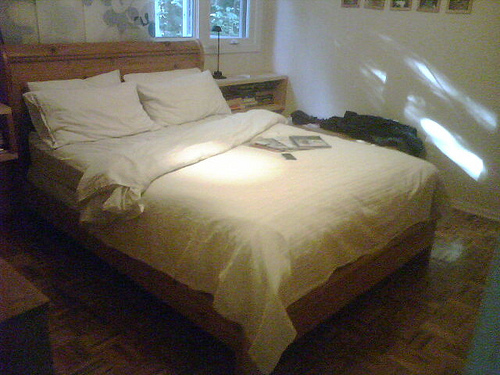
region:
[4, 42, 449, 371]
bed on a wood floor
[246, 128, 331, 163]
magazines fanned out on a bed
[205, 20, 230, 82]
tabletop lamp beside bed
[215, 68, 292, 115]
bookshelf next to bed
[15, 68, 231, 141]
four pillows at head of bed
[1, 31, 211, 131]
wooden headboard against wall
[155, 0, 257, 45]
windows inside bedroom next to bed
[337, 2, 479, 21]
part of art on wall of bedroom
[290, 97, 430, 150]
clothes on table next to bed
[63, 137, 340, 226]
part of a comforter on bed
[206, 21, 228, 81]
black metal light next to bed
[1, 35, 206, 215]
light brown wooden headboard behind bed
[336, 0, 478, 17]
row of small rectangular pictures on wall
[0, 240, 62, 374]
brown wooden dresser next to bed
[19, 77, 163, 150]
rectangular white pillow on bed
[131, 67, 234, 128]
rectangular white pillow on bed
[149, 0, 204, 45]
clear rectangular window near bed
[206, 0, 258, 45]
clear rectangular window near bed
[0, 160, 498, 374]
brown and light brown wooden floor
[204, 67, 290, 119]
beige night stand next to bed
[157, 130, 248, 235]
White color bed spread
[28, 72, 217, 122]
White color pillow cover with pillow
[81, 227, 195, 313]
Wooden type cot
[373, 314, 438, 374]
Wooden type floor tiles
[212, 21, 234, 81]
Black color night lamp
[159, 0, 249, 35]
Glass windows with wooden frame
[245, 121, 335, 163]
Books kept in the bed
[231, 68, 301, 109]
Wooden racks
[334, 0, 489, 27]
Photo frames hanging on the wall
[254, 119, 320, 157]
two books on bed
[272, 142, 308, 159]
remote control on bed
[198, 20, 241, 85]
small lamp near bed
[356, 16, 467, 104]
white wall in bedroom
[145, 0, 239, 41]
white frame around window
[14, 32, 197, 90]
brown head of bed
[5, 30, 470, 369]
this is a bed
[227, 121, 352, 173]
magazines on a bed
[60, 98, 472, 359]
the comforter is white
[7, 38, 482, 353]
the bed is made of wood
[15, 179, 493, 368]
the floor is made of wood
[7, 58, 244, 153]
here are some pillows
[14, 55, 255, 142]
the pillowcases are white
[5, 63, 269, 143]
these are white pillows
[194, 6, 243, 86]
a small black lamp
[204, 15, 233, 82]
the lamp has a thin post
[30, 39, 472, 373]
bed on the side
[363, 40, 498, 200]
sunlight on the wall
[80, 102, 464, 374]
white cover on the bed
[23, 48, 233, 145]
a group of pillows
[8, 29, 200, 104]
brown headboard on bed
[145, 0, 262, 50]
window on the side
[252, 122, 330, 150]
books on the bed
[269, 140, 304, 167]
phone on the bed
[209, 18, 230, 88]
lamp on the side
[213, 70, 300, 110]
a shelf next to the bed